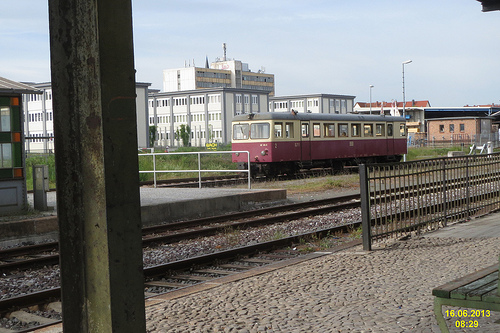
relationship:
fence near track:
[358, 150, 499, 255] [1, 191, 498, 329]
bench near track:
[426, 256, 498, 331] [12, 147, 494, 324]